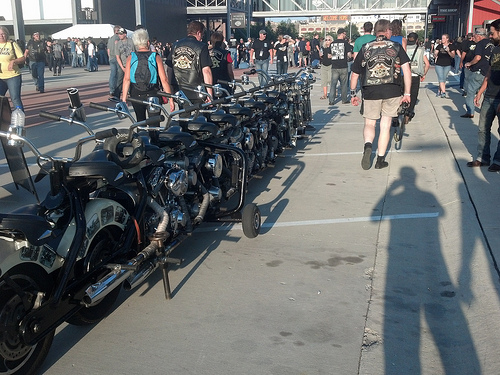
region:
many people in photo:
[51, 12, 457, 132]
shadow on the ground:
[346, 134, 461, 265]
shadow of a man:
[337, 162, 446, 242]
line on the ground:
[331, 236, 398, 330]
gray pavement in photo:
[217, 250, 329, 337]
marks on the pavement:
[288, 240, 358, 283]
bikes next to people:
[26, 83, 270, 259]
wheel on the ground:
[231, 187, 281, 255]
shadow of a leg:
[363, 292, 431, 374]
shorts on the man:
[346, 82, 405, 142]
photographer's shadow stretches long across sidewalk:
[371, 166, 479, 374]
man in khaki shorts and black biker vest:
[346, 19, 413, 170]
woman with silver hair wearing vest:
[120, 28, 175, 124]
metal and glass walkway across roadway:
[186, 1, 431, 15]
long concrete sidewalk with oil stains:
[40, 67, 498, 374]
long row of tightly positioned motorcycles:
[0, 68, 317, 374]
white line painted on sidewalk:
[190, 209, 441, 232]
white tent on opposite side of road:
[50, 22, 134, 40]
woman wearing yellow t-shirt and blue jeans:
[0, 25, 27, 114]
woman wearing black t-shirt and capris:
[430, 32, 456, 97]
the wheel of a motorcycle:
[2, 267, 59, 373]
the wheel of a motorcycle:
[55, 219, 127, 329]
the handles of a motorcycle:
[1, 120, 119, 172]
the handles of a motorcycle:
[34, 105, 166, 148]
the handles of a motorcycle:
[83, 100, 203, 137]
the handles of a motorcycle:
[148, 88, 250, 116]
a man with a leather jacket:
[165, 31, 210, 96]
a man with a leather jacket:
[200, 47, 233, 86]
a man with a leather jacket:
[355, 38, 408, 92]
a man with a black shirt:
[329, 38, 351, 69]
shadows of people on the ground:
[366, 77, 496, 374]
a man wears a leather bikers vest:
[339, 18, 414, 173]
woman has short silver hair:
[114, 25, 176, 125]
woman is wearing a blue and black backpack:
[117, 26, 173, 124]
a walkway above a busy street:
[251, 0, 430, 21]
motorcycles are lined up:
[3, 43, 318, 373]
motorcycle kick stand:
[150, 245, 186, 302]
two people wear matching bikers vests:
[170, 15, 237, 93]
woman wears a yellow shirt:
[0, 23, 32, 126]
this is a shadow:
[368, 141, 486, 373]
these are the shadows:
[366, 102, 498, 374]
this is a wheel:
[46, 203, 141, 328]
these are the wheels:
[3, 151, 178, 373]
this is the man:
[336, 9, 416, 178]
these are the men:
[89, 16, 459, 169]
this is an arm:
[348, 55, 365, 110]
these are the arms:
[343, 46, 418, 116]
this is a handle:
[29, 103, 102, 148]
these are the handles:
[36, 81, 192, 133]